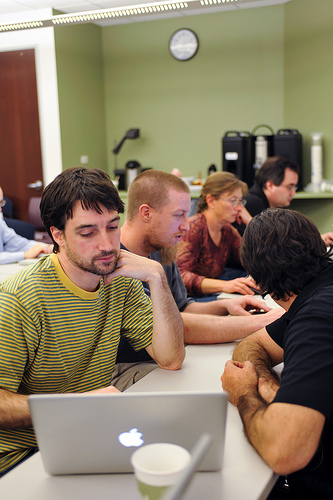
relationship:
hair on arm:
[233, 337, 280, 390] [230, 311, 288, 403]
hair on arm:
[236, 389, 271, 437] [230, 311, 288, 403]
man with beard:
[111, 169, 282, 345] [158, 241, 180, 265]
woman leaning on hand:
[188, 162, 250, 277] [233, 204, 257, 225]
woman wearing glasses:
[175, 171, 261, 297] [210, 194, 247, 207]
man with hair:
[252, 149, 298, 213] [261, 158, 282, 176]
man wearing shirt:
[218, 206, 331, 498] [265, 261, 331, 499]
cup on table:
[129, 443, 216, 499] [18, 256, 292, 495]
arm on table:
[238, 400, 330, 478] [0, 295, 288, 498]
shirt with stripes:
[2, 254, 159, 473] [47, 317, 88, 323]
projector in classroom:
[110, 128, 153, 192] [15, 130, 331, 442]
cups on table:
[299, 131, 332, 194] [1, 248, 329, 495]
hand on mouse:
[223, 277, 263, 295] [233, 286, 262, 295]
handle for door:
[28, 178, 44, 188] [0, 45, 43, 222]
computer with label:
[20, 387, 231, 489] [118, 426, 142, 447]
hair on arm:
[238, 392, 269, 441] [238, 400, 330, 478]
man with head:
[120, 170, 281, 347] [126, 168, 189, 249]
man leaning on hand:
[0, 167, 186, 479] [103, 247, 168, 285]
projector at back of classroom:
[112, 127, 152, 191] [0, 0, 333, 499]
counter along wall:
[105, 174, 331, 212] [200, 10, 321, 167]